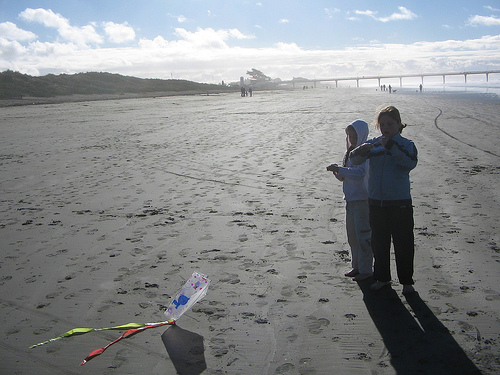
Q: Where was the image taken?
A: It was taken at the beach.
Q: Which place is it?
A: It is a beach.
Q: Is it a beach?
A: Yes, it is a beach.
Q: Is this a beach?
A: Yes, it is a beach.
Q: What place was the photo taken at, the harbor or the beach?
A: It was taken at the beach.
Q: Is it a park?
A: No, it is a beach.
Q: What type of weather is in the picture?
A: It is cloudy.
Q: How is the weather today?
A: It is cloudy.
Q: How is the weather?
A: It is cloudy.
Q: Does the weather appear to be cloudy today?
A: Yes, it is cloudy.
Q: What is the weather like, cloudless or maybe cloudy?
A: It is cloudy.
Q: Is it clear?
A: No, it is cloudy.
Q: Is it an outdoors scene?
A: Yes, it is outdoors.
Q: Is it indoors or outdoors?
A: It is outdoors.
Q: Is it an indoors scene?
A: No, it is outdoors.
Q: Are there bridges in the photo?
A: Yes, there is a bridge.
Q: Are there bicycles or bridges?
A: Yes, there is a bridge.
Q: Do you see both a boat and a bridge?
A: No, there is a bridge but no boats.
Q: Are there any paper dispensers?
A: No, there are no paper dispensers.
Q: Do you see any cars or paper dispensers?
A: No, there are no paper dispensers or cars.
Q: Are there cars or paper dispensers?
A: No, there are no paper dispensers or cars.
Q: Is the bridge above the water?
A: Yes, the bridge is above the water.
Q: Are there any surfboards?
A: No, there are no surfboards.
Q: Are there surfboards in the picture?
A: No, there are no surfboards.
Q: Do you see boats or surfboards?
A: No, there are no surfboards or boats.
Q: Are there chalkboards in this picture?
A: No, there are no chalkboards.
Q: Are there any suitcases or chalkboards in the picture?
A: No, there are no chalkboards or suitcases.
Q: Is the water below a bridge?
A: Yes, the water is below a bridge.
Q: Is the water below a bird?
A: No, the water is below a bridge.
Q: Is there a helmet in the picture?
A: No, there are no helmets.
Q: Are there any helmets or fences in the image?
A: No, there are no helmets or fences.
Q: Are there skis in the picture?
A: No, there are no skis.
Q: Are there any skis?
A: No, there are no skis.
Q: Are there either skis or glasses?
A: No, there are no skis or glasses.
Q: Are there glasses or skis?
A: No, there are no skis or glasses.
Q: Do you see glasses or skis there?
A: No, there are no skis or glasses.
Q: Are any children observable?
A: Yes, there is a child.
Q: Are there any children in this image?
A: Yes, there is a child.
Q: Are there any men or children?
A: Yes, there is a child.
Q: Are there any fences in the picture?
A: No, there are no fences.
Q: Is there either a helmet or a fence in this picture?
A: No, there are no fences or helmets.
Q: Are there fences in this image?
A: No, there are no fences.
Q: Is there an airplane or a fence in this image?
A: No, there are no fences or airplanes.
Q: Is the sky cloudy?
A: Yes, the sky is cloudy.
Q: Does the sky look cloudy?
A: Yes, the sky is cloudy.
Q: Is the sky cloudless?
A: No, the sky is cloudy.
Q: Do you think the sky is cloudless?
A: No, the sky is cloudy.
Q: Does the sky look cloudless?
A: No, the sky is cloudy.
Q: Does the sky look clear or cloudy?
A: The sky is cloudy.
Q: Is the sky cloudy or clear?
A: The sky is cloudy.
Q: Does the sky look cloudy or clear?
A: The sky is cloudy.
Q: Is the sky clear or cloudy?
A: The sky is cloudy.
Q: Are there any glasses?
A: No, there are no glasses.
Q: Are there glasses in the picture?
A: No, there are no glasses.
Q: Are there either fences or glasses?
A: No, there are no glasses or fences.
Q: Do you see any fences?
A: No, there are no fences.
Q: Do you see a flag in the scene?
A: No, there are no flags.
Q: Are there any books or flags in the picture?
A: No, there are no flags or books.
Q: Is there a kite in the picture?
A: Yes, there is a kite.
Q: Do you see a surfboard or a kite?
A: Yes, there is a kite.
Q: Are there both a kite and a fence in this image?
A: No, there is a kite but no fences.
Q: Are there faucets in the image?
A: No, there are no faucets.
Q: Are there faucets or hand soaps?
A: No, there are no faucets or hand soaps.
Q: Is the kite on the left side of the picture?
A: Yes, the kite is on the left of the image.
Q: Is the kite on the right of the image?
A: No, the kite is on the left of the image.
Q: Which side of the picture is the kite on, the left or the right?
A: The kite is on the left of the image.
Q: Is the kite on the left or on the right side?
A: The kite is on the left of the image.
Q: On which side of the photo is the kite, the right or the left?
A: The kite is on the left of the image.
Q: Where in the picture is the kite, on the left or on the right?
A: The kite is on the left of the image.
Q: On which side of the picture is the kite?
A: The kite is on the left of the image.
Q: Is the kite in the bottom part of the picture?
A: Yes, the kite is in the bottom of the image.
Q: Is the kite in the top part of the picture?
A: No, the kite is in the bottom of the image.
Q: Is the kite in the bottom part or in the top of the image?
A: The kite is in the bottom of the image.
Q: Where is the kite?
A: The kite is on the ground.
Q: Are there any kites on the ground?
A: Yes, there is a kite on the ground.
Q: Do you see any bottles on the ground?
A: No, there is a kite on the ground.